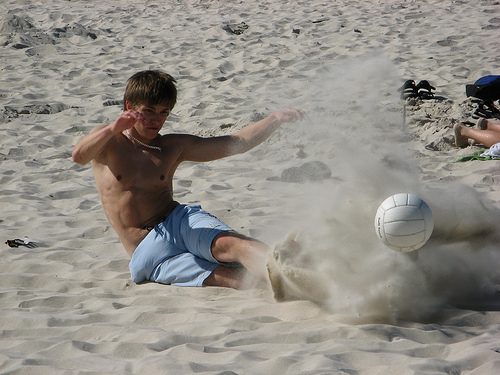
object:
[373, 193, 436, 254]
ball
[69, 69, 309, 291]
boy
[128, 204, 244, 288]
shorts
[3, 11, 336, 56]
sand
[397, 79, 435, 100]
shoes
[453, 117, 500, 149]
person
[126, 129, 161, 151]
necklace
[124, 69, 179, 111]
hair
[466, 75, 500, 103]
bag